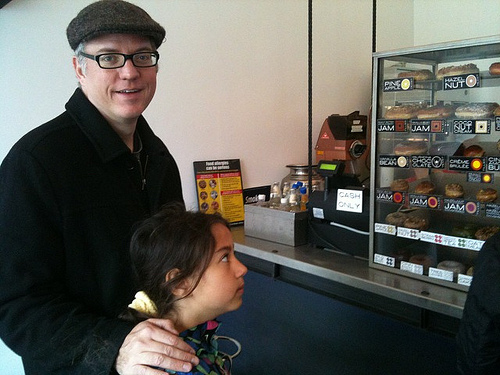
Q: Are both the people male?
A: No, they are both male and female.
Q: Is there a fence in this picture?
A: No, there are no fences.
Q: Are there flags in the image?
A: No, there are no flags.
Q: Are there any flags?
A: No, there are no flags.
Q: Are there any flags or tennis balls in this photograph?
A: No, there are no flags or tennis balls.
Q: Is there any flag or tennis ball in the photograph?
A: No, there are no flags or tennis balls.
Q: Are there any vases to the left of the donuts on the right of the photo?
A: Yes, there is a vase to the left of the doughnuts.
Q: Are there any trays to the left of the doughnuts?
A: No, there is a vase to the left of the doughnuts.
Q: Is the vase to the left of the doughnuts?
A: Yes, the vase is to the left of the doughnuts.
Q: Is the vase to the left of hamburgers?
A: No, the vase is to the left of the doughnuts.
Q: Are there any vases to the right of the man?
A: Yes, there is a vase to the right of the man.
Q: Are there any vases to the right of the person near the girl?
A: Yes, there is a vase to the right of the man.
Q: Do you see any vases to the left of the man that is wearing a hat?
A: No, the vase is to the right of the man.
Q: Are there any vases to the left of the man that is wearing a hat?
A: No, the vase is to the right of the man.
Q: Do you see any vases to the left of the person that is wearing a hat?
A: No, the vase is to the right of the man.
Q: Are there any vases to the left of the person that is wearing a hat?
A: No, the vase is to the right of the man.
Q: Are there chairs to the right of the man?
A: No, there is a vase to the right of the man.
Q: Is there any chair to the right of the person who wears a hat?
A: No, there is a vase to the right of the man.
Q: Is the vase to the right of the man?
A: Yes, the vase is to the right of the man.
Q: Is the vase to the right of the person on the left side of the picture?
A: Yes, the vase is to the right of the man.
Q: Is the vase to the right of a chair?
A: No, the vase is to the right of the man.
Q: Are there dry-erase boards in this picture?
A: No, there are no dry-erase boards.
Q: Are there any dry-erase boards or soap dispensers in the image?
A: No, there are no dry-erase boards or soap dispensers.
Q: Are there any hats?
A: Yes, there is a hat.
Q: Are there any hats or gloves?
A: Yes, there is a hat.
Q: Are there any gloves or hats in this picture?
A: Yes, there is a hat.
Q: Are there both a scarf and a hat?
A: No, there is a hat but no scarves.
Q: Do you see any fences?
A: No, there are no fences.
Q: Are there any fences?
A: No, there are no fences.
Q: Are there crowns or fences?
A: No, there are no fences or crowns.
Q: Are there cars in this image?
A: No, there are no cars.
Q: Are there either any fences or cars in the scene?
A: No, there are no cars or fences.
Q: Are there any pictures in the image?
A: No, there are no pictures.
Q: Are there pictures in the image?
A: No, there are no pictures.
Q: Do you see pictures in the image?
A: No, there are no pictures.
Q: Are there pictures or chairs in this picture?
A: No, there are no pictures or chairs.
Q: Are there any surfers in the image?
A: No, there are no surfers.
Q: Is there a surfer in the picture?
A: No, there are no surfers.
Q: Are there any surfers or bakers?
A: No, there are no surfers or bakers.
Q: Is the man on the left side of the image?
A: Yes, the man is on the left of the image.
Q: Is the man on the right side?
A: No, the man is on the left of the image.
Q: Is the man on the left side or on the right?
A: The man is on the left of the image.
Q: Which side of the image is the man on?
A: The man is on the left of the image.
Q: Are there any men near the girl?
A: Yes, there is a man near the girl.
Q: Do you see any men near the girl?
A: Yes, there is a man near the girl.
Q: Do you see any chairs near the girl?
A: No, there is a man near the girl.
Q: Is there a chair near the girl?
A: No, there is a man near the girl.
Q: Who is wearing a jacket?
A: The man is wearing a jacket.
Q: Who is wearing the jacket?
A: The man is wearing a jacket.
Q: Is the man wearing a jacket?
A: Yes, the man is wearing a jacket.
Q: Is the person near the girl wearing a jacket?
A: Yes, the man is wearing a jacket.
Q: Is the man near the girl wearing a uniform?
A: No, the man is wearing a jacket.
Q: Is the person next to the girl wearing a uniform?
A: No, the man is wearing a jacket.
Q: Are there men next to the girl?
A: Yes, there is a man next to the girl.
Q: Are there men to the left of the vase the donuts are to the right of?
A: Yes, there is a man to the left of the vase.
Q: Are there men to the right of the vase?
A: No, the man is to the left of the vase.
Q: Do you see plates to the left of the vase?
A: No, there is a man to the left of the vase.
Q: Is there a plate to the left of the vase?
A: No, there is a man to the left of the vase.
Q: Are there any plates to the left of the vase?
A: No, there is a man to the left of the vase.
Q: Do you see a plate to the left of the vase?
A: No, there is a man to the left of the vase.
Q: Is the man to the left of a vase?
A: Yes, the man is to the left of a vase.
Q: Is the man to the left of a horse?
A: No, the man is to the left of a vase.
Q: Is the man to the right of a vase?
A: No, the man is to the left of a vase.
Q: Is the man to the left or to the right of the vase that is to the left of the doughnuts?
A: The man is to the left of the vase.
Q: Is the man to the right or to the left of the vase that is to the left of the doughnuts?
A: The man is to the left of the vase.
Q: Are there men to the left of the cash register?
A: Yes, there is a man to the left of the cash register.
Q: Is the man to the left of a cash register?
A: Yes, the man is to the left of a cash register.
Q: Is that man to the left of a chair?
A: No, the man is to the left of a cash register.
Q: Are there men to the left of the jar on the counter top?
A: Yes, there is a man to the left of the jar.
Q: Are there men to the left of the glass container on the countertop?
A: Yes, there is a man to the left of the jar.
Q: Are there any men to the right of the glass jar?
A: No, the man is to the left of the jar.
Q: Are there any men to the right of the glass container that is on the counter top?
A: No, the man is to the left of the jar.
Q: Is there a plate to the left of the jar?
A: No, there is a man to the left of the jar.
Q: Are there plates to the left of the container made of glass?
A: No, there is a man to the left of the jar.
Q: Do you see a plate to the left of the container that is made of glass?
A: No, there is a man to the left of the jar.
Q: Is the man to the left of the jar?
A: Yes, the man is to the left of the jar.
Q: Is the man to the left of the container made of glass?
A: Yes, the man is to the left of the jar.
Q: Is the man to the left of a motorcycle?
A: No, the man is to the left of the jar.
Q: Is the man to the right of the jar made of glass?
A: No, the man is to the left of the jar.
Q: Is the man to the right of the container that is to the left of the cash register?
A: No, the man is to the left of the jar.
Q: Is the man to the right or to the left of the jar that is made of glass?
A: The man is to the left of the jar.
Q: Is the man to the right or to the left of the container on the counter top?
A: The man is to the left of the jar.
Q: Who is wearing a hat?
A: The man is wearing a hat.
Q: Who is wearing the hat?
A: The man is wearing a hat.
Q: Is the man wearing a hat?
A: Yes, the man is wearing a hat.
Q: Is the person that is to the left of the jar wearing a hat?
A: Yes, the man is wearing a hat.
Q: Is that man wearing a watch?
A: No, the man is wearing a hat.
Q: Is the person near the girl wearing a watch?
A: No, the man is wearing a hat.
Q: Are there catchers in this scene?
A: No, there are no catchers.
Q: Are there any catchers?
A: No, there are no catchers.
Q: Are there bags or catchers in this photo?
A: No, there are no catchers or bags.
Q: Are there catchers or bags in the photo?
A: No, there are no catchers or bags.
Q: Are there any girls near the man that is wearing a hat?
A: Yes, there is a girl near the man.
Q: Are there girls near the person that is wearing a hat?
A: Yes, there is a girl near the man.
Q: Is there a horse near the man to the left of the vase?
A: No, there is a girl near the man.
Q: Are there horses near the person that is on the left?
A: No, there is a girl near the man.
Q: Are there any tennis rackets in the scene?
A: No, there are no tennis rackets.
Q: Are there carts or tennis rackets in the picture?
A: No, there are no tennis rackets or carts.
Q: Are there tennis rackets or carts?
A: No, there are no tennis rackets or carts.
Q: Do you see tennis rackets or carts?
A: No, there are no tennis rackets or carts.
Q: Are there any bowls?
A: No, there are no bowls.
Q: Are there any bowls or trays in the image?
A: No, there are no bowls or trays.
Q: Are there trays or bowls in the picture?
A: No, there are no bowls or trays.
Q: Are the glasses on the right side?
A: No, the glasses are on the left of the image.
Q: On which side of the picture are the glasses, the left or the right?
A: The glasses are on the left of the image.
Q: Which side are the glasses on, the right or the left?
A: The glasses are on the left of the image.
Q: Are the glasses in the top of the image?
A: Yes, the glasses are in the top of the image.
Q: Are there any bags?
A: No, there are no bags.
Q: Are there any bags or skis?
A: No, there are no bags or skis.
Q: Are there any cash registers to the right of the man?
A: Yes, there is a cash register to the right of the man.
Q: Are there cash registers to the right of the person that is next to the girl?
A: Yes, there is a cash register to the right of the man.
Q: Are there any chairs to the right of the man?
A: No, there is a cash register to the right of the man.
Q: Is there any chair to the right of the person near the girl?
A: No, there is a cash register to the right of the man.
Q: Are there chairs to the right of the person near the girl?
A: No, there is a cash register to the right of the man.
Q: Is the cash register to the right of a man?
A: Yes, the cash register is to the right of a man.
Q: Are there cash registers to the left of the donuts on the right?
A: Yes, there is a cash register to the left of the donuts.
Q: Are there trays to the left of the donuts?
A: No, there is a cash register to the left of the donuts.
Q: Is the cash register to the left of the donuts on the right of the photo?
A: Yes, the cash register is to the left of the donuts.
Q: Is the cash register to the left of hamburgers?
A: No, the cash register is to the left of the donuts.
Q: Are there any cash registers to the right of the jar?
A: Yes, there is a cash register to the right of the jar.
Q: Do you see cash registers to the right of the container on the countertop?
A: Yes, there is a cash register to the right of the jar.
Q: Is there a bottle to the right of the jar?
A: No, there is a cash register to the right of the jar.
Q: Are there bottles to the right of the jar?
A: No, there is a cash register to the right of the jar.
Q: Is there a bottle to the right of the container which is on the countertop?
A: No, there is a cash register to the right of the jar.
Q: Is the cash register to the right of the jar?
A: Yes, the cash register is to the right of the jar.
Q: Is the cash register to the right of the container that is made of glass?
A: Yes, the cash register is to the right of the jar.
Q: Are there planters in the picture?
A: No, there are no planters.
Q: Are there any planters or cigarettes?
A: No, there are no planters or cigarettes.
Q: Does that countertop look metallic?
A: Yes, the countertop is metallic.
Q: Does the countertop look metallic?
A: Yes, the countertop is metallic.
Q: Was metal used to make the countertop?
A: Yes, the countertop is made of metal.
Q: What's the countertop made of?
A: The counter top is made of metal.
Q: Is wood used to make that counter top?
A: No, the counter top is made of metal.